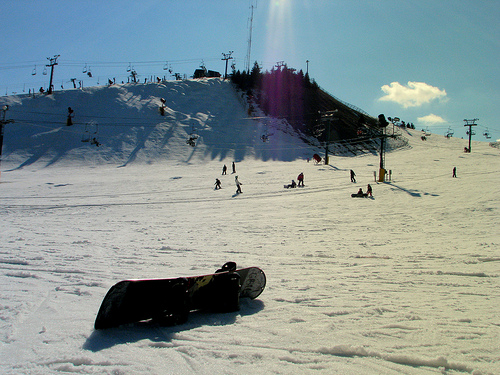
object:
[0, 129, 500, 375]
ground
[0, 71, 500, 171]
hill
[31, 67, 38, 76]
ski lifts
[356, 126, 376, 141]
ski lifts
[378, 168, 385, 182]
post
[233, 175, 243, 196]
people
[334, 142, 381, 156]
fence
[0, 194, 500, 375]
snow area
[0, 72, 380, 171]
hill side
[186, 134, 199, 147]
snowboarder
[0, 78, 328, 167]
down hill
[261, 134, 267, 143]
snowboarder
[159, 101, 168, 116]
snowboarder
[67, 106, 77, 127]
snowboarder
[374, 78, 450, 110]
cloud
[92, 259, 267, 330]
board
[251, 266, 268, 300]
edge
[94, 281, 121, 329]
tip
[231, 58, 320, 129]
forest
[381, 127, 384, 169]
pole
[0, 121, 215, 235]
snow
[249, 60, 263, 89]
trees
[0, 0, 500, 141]
sky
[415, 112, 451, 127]
clouds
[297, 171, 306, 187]
skiers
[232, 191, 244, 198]
skis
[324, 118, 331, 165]
poles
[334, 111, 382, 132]
cables